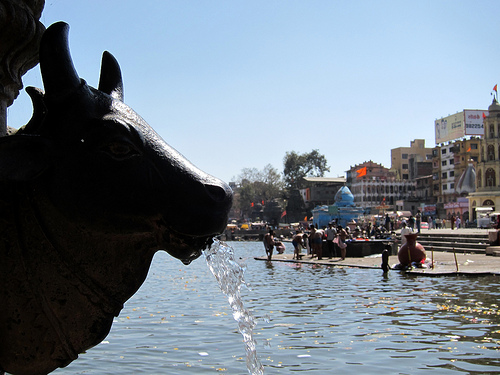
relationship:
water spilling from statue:
[204, 235, 266, 374] [0, 20, 233, 374]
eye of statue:
[99, 137, 141, 159] [0, 20, 233, 374]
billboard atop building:
[433, 110, 467, 144] [434, 136, 484, 218]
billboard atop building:
[462, 108, 489, 136] [434, 136, 484, 218]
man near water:
[261, 231, 276, 261] [49, 238, 500, 374]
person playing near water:
[289, 230, 309, 261] [49, 238, 500, 374]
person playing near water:
[310, 229, 326, 261] [49, 238, 500, 374]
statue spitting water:
[0, 20, 233, 374] [204, 235, 266, 374]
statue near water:
[0, 20, 233, 374] [49, 238, 500, 374]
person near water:
[289, 230, 309, 261] [49, 238, 500, 374]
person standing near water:
[289, 230, 309, 261] [49, 238, 500, 374]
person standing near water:
[310, 229, 326, 261] [49, 238, 500, 374]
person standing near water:
[335, 224, 351, 259] [49, 238, 500, 374]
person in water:
[381, 246, 391, 278] [49, 238, 500, 374]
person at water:
[289, 230, 309, 261] [49, 238, 500, 374]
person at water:
[310, 229, 326, 261] [49, 238, 500, 374]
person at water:
[335, 224, 351, 259] [49, 238, 500, 374]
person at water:
[381, 246, 391, 278] [49, 238, 500, 374]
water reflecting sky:
[49, 238, 500, 374] [6, 0, 498, 188]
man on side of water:
[261, 231, 276, 261] [49, 238, 500, 374]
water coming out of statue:
[204, 235, 266, 374] [0, 20, 233, 374]